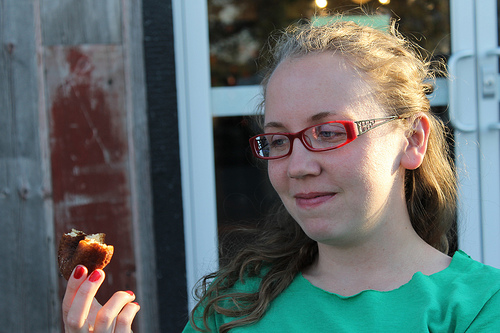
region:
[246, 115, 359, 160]
red framed eye glasses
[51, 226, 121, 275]
half of a donut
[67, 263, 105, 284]
red fingernail polish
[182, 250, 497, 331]
a green cotton shirt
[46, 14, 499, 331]
a woman looking at half of a donut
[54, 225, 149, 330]
a hand holding a donut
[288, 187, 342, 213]
red lips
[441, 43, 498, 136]
chrome handles on a door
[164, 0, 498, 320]
a glass and metal door behind the woman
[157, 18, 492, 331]
a woman standing in front of a building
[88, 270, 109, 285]
red fingernail on girl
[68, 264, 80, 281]
red fingernail on girl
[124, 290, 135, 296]
red fingernail on girl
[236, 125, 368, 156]
red glasses on girl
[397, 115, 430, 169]
left ear on girl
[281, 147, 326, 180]
nose on girl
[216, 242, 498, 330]
girl wearing green shirt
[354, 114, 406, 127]
metal side of glasses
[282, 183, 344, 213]
girl with smile on face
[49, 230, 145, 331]
piece of pastry in hand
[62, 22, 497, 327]
girl wearing a green shirt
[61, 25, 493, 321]
girl wearing red glasses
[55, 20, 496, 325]
girl holding eaten donut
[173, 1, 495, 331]
large metal doors behind girl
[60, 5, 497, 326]
a girl wearing red fingernail polish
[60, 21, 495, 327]
girl smiling at a donut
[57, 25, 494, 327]
girl standing in front of doors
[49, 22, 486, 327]
girl standing in front of building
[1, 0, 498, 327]
building with red missing paint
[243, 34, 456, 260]
blonde girl in red glasses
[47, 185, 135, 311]
girl is looking at bitten doughnut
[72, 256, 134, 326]
girl's nails are polished bright red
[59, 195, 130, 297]
the doughnut is brown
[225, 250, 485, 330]
the girl is wearing an aqua shirt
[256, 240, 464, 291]
the collar has been removed from the shirt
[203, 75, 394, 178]
the girl is wearing red glasses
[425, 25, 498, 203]
there are glass doors behind the girl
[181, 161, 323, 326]
the girl's hair is on her shoulder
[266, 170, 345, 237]
the girl has a smile on her face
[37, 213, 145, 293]
a piece of food in the girl's hand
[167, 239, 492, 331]
girl wearing a light blue top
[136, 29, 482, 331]
brown hair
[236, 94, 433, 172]
lady wearing glasses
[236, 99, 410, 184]
glass frames are red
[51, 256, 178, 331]
woman wearing red nail polish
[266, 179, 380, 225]
woman is smirking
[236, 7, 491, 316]
woman is looking at the food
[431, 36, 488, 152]
door handle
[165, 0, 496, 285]
door is behind the woman